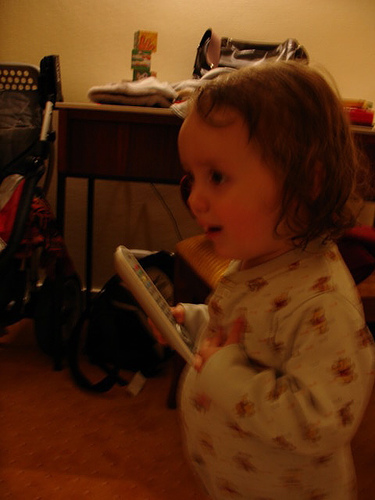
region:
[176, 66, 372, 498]
little girl wearing pajamas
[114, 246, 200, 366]
remote control in the girl's hand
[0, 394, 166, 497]
carpeted flooring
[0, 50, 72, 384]
folded-up stroller sitting on the floor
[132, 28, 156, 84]
stacked blocks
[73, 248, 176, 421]
duffle bag sitting on the floor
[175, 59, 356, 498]
little girl with brown hair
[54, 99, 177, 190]
brown wooden table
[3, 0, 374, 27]
white wall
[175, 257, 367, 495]
out of focus kids clothing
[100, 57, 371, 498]
small child with brown hair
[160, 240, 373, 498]
child's shirt with red pattern designs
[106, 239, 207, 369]
electronic device in child's hand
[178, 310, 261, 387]
child's left hand on chest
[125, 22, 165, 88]
stack of blocks on table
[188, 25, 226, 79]
brown strap on table top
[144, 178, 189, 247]
electrical cord behind table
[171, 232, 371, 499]
child's long sleeved shirt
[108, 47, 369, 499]
small child facing left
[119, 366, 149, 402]
white tag on black bag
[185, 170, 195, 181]
the eye of a child's face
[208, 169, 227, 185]
the eye of a child's face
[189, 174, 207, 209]
the nose on the face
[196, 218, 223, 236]
the mouth on the face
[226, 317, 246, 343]
the thumb on a hand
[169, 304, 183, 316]
the thumb on a hand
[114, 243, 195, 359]
the grey clicker in a hand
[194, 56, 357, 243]
the short brown hair on a head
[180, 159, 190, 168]
the eyebrow on the face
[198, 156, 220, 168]
the eyebrow on the face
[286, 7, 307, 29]
Small section of the white wall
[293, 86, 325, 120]
Brunette hair of the baby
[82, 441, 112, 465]
Brown ground in the house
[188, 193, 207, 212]
Nose of the baby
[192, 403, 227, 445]
Decorative pajamas of the baby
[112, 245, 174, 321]
Top and mid section of the remote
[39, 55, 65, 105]
Black top of the guitar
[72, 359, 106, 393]
Black strap of the bag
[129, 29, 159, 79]
Three blocks on the desk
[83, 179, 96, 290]
One of the black legs on the desk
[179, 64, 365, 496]
a child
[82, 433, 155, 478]
the carpet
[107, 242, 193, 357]
a controller the child is holding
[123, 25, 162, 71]
blocks on the table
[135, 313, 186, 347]
child is holding a controller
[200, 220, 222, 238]
mouth is open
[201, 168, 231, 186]
left eye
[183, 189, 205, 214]
the childs nose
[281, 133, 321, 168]
the hair is brown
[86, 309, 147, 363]
a bag